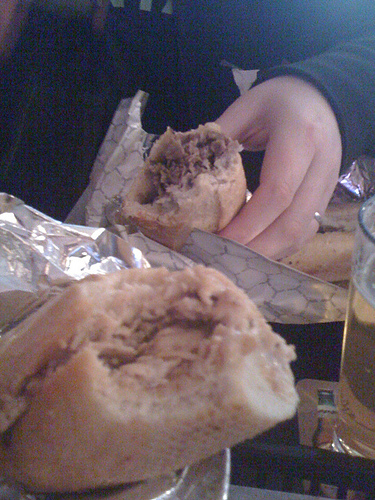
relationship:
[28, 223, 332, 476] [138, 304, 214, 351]
sandwich has meat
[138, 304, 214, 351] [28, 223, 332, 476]
meat inside sandwich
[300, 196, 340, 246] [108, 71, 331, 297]
ring on person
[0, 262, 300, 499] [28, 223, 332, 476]
sandwich of sandwich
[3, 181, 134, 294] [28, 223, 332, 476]
wrapper for sandwich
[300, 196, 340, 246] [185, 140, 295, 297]
ring on finger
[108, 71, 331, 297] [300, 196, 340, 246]
person has ring